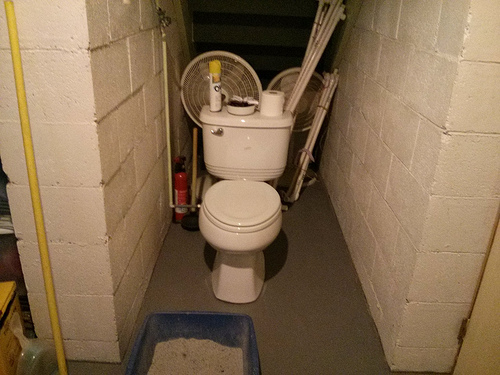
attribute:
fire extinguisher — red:
[171, 157, 194, 219]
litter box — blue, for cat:
[135, 303, 273, 373]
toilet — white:
[197, 93, 292, 308]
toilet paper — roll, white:
[257, 91, 290, 119]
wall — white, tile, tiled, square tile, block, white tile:
[32, 9, 183, 350]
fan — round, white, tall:
[184, 53, 271, 137]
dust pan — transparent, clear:
[3, 319, 54, 374]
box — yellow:
[3, 292, 37, 367]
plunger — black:
[187, 125, 210, 240]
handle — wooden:
[188, 125, 202, 209]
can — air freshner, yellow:
[202, 58, 228, 116]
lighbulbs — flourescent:
[291, 7, 336, 143]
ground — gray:
[187, 255, 380, 374]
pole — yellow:
[4, 24, 69, 327]